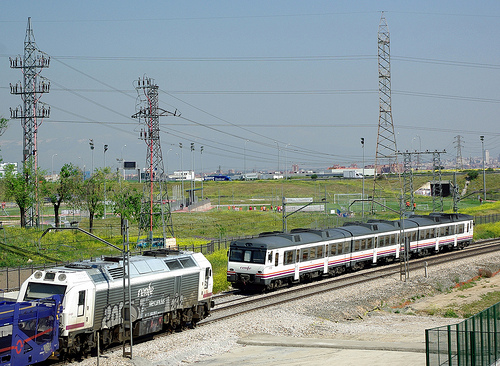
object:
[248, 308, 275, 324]
gravel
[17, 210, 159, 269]
grass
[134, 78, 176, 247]
pole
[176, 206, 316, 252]
grass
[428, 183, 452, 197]
entrance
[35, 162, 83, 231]
tree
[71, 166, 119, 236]
tree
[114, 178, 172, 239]
tree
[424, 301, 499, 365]
fence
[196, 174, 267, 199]
grass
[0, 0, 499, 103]
sky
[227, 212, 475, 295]
trains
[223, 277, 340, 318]
rails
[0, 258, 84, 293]
fence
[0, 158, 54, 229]
trees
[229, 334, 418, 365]
ground